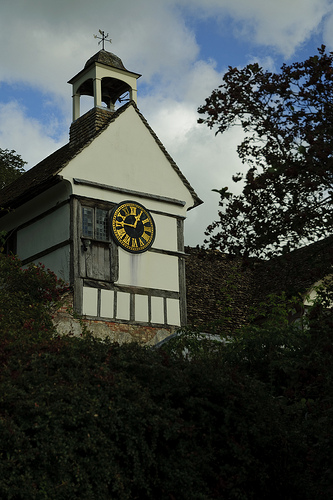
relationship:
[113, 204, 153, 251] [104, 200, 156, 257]
numbers on clock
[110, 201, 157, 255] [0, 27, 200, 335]
clock on clock tower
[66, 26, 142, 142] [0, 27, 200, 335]
cupola on clock tower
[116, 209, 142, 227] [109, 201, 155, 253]
hands on clock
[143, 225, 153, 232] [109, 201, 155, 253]
roman numeral on clock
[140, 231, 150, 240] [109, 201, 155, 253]
roman numeral on clock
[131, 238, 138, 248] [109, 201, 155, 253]
roman numeral on clock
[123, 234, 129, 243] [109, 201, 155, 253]
roman numeral on clock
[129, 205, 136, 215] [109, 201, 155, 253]
roman numeral on clock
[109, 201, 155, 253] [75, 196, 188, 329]
clock on wall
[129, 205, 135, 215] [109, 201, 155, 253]
roman numeral on clock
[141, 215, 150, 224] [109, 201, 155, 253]
roman numeral on clock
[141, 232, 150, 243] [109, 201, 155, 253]
roman numeral on clock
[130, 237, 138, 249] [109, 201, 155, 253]
roman numeral on clock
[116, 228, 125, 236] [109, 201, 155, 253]
roman numeral on clock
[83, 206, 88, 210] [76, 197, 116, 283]
pane on window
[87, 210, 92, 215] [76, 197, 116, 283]
pane on window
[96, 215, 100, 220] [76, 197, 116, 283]
pane on window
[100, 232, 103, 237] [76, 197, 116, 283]
pane on window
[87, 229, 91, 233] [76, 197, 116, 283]
pane on window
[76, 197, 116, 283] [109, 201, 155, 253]
window next to clock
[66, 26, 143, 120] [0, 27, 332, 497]
cupola on top of clock tower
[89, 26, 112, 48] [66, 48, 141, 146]
vane on top of cupola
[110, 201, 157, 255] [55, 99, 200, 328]
clock on wall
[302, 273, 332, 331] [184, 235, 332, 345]
archway in wall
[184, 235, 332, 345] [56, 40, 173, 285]
wall next to tower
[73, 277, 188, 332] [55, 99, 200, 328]
frame on wall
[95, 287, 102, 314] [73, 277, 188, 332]
slat on frame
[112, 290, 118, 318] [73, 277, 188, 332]
slat on frame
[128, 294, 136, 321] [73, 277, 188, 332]
slat on frame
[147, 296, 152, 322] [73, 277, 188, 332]
slat on frame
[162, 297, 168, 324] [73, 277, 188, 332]
slat on frame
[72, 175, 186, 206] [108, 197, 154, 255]
slat above clock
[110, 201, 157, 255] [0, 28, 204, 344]
clock on building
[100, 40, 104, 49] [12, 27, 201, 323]
pole on top of building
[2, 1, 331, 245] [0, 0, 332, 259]
white clouds in sky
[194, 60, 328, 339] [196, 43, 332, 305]
leaves on tree